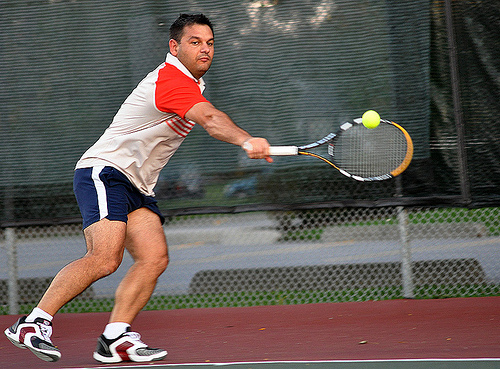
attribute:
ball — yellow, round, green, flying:
[357, 105, 382, 131]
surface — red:
[0, 293, 498, 367]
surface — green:
[96, 360, 497, 366]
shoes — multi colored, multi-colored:
[3, 310, 170, 366]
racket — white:
[268, 117, 413, 184]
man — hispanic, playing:
[4, 10, 275, 362]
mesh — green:
[6, 1, 430, 187]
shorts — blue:
[71, 161, 162, 231]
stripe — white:
[90, 167, 106, 220]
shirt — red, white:
[73, 54, 207, 194]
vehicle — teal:
[218, 171, 257, 204]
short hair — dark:
[168, 13, 214, 43]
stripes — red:
[164, 111, 194, 138]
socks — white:
[24, 306, 132, 339]